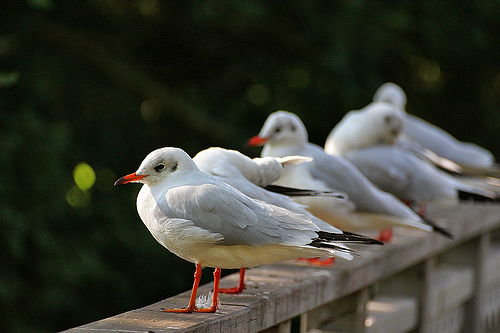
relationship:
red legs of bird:
[159, 260, 224, 317] [113, 144, 385, 314]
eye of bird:
[153, 159, 166, 173] [200, 138, 333, 217]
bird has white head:
[113, 144, 385, 314] [113, 139, 201, 194]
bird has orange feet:
[113, 144, 385, 314] [164, 293, 223, 315]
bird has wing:
[144, 156, 246, 271] [211, 197, 276, 240]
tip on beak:
[114, 176, 123, 185] [112, 171, 144, 191]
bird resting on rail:
[112, 146, 363, 313] [63, 257, 375, 331]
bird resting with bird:
[112, 146, 363, 313] [247, 103, 455, 246]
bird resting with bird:
[112, 146, 363, 313] [323, 101, 498, 219]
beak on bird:
[113, 173, 140, 185] [118, 137, 351, 310]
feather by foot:
[196, 291, 213, 308] [195, 303, 220, 315]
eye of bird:
[152, 161, 168, 176] [131, 168, 323, 273]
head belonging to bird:
[365, 96, 404, 147] [321, 102, 484, 218]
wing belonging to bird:
[151, 182, 318, 251] [113, 144, 385, 314]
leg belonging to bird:
[158, 259, 204, 314] [118, 137, 351, 310]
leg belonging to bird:
[191, 257, 221, 313] [118, 137, 351, 310]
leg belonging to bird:
[295, 251, 320, 261] [246, 109, 448, 236]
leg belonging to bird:
[309, 250, 338, 265] [246, 109, 448, 236]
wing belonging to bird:
[307, 150, 408, 220] [240, 107, 457, 239]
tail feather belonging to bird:
[419, 213, 456, 241] [240, 107, 457, 239]